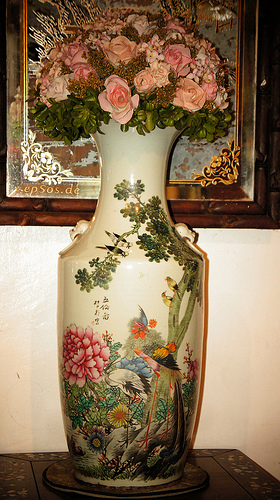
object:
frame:
[0, 0, 280, 232]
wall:
[0, 223, 280, 483]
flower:
[104, 401, 132, 429]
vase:
[57, 118, 211, 491]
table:
[0, 444, 280, 499]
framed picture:
[27, 3, 239, 184]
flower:
[96, 73, 140, 126]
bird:
[102, 351, 154, 451]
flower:
[59, 319, 114, 388]